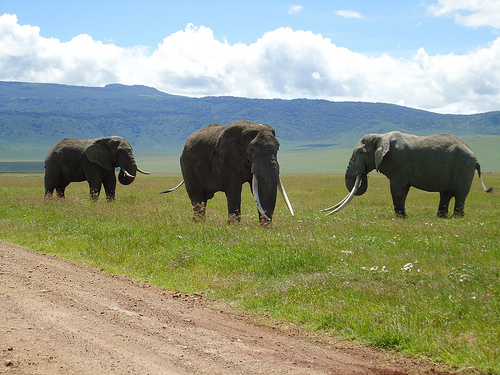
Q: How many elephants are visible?
A: Three.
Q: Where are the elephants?
A: In the wild.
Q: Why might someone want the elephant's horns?
A: They are ivory.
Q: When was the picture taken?
A: Daylight.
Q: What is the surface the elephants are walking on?
A: Grass.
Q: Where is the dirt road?
A: Next to the grass.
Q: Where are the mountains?
A: Behind the elephants.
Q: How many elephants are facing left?
A: One.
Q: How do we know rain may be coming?
A: There are clouds in the sky.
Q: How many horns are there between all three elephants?
A: Six.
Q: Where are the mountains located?
A: Behind the hills.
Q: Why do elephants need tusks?
A: For protection.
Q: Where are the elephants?
A: In a grassy field.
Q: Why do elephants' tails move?
A: To swat insects.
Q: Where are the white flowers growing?
A: In a grassy field.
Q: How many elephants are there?
A: Three.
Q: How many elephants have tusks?
A: Three.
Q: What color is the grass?
A: Green.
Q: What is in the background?
A: Mountains.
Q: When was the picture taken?
A: Daytime.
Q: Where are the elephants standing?
A: In Grass.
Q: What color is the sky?
A: Blue.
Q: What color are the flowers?
A: White.